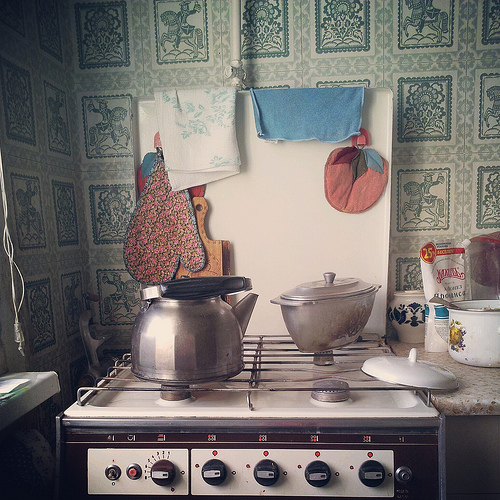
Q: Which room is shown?
A: It is a kitchen.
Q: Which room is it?
A: It is a kitchen.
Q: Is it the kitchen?
A: Yes, it is the kitchen.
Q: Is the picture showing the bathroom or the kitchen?
A: It is showing the kitchen.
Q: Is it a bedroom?
A: No, it is a kitchen.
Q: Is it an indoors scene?
A: Yes, it is indoors.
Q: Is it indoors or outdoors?
A: It is indoors.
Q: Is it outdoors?
A: No, it is indoors.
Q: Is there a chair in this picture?
A: No, there are no chairs.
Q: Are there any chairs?
A: No, there are no chairs.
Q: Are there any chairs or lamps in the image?
A: No, there are no chairs or lamps.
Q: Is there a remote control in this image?
A: Yes, there is a remote control.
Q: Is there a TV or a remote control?
A: Yes, there is a remote control.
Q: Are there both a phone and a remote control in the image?
A: No, there is a remote control but no phones.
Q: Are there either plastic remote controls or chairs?
A: Yes, there is a plastic remote control.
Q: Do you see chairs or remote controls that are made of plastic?
A: Yes, the remote control is made of plastic.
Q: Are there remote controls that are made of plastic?
A: Yes, there is a remote control that is made of plastic.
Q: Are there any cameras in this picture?
A: No, there are no cameras.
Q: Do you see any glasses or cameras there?
A: No, there are no cameras or glasses.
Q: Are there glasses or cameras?
A: No, there are no cameras or glasses.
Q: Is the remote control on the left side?
A: Yes, the remote control is on the left of the image.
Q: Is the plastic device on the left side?
A: Yes, the remote control is on the left of the image.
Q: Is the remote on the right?
A: No, the remote is on the left of the image.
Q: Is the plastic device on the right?
A: No, the remote is on the left of the image.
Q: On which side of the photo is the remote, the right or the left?
A: The remote is on the left of the image.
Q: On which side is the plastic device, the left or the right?
A: The remote is on the left of the image.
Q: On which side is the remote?
A: The remote is on the left of the image.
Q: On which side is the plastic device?
A: The remote is on the left of the image.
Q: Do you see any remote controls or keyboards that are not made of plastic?
A: No, there is a remote control but it is made of plastic.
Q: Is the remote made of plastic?
A: Yes, the remote is made of plastic.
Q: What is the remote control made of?
A: The remote control is made of plastic.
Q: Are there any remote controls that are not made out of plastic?
A: No, there is a remote control but it is made of plastic.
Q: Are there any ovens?
A: Yes, there is an oven.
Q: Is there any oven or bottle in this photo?
A: Yes, there is an oven.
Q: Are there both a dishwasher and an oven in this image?
A: No, there is an oven but no dishwashers.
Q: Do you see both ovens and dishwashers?
A: No, there is an oven but no dishwashers.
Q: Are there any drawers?
A: No, there are no drawers.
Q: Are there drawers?
A: No, there are no drawers.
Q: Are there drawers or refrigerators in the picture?
A: No, there are no drawers or refrigerators.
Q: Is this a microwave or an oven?
A: This is an oven.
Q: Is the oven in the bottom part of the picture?
A: Yes, the oven is in the bottom of the image.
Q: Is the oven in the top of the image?
A: No, the oven is in the bottom of the image.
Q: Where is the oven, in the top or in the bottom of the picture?
A: The oven is in the bottom of the image.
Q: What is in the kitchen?
A: The oven is in the kitchen.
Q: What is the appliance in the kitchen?
A: The appliance is an oven.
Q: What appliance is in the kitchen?
A: The appliance is an oven.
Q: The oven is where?
A: The oven is in the kitchen.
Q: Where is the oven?
A: The oven is in the kitchen.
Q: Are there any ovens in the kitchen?
A: Yes, there is an oven in the kitchen.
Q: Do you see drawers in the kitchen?
A: No, there is an oven in the kitchen.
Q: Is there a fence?
A: No, there are no fences.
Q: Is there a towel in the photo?
A: Yes, there is a towel.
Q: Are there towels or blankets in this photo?
A: Yes, there is a towel.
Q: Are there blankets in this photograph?
A: No, there are no blankets.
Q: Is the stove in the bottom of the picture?
A: Yes, the stove is in the bottom of the image.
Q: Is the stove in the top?
A: No, the stove is in the bottom of the image.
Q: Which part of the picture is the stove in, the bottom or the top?
A: The stove is in the bottom of the image.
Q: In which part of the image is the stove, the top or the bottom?
A: The stove is in the bottom of the image.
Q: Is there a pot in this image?
A: Yes, there is a pot.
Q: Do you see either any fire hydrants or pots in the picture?
A: Yes, there is a pot.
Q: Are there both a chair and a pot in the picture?
A: No, there is a pot but no chairs.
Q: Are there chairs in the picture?
A: No, there are no chairs.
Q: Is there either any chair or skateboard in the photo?
A: No, there are no chairs or skateboards.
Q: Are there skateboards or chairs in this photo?
A: No, there are no chairs or skateboards.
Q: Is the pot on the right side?
A: Yes, the pot is on the right of the image.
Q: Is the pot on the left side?
A: No, the pot is on the right of the image.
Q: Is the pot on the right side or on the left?
A: The pot is on the right of the image.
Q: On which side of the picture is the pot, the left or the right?
A: The pot is on the right of the image.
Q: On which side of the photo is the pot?
A: The pot is on the right of the image.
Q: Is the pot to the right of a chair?
A: No, the pot is to the right of the container.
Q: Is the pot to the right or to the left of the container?
A: The pot is to the right of the container.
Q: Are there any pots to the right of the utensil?
A: Yes, there is a pot to the right of the utensil.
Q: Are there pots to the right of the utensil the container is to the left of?
A: Yes, there is a pot to the right of the utensil.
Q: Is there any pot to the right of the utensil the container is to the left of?
A: Yes, there is a pot to the right of the utensil.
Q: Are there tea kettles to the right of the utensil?
A: No, there is a pot to the right of the utensil.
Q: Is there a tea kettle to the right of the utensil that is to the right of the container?
A: No, there is a pot to the right of the utensil.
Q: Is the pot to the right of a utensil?
A: Yes, the pot is to the right of a utensil.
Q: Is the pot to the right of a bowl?
A: No, the pot is to the right of a utensil.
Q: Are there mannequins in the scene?
A: No, there are no mannequins.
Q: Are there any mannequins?
A: No, there are no mannequins.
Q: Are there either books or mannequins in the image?
A: No, there are no mannequins or books.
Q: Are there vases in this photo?
A: No, there are no vases.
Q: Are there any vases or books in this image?
A: No, there are no vases or books.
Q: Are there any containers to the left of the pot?
A: Yes, there is a container to the left of the pot.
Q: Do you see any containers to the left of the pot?
A: Yes, there is a container to the left of the pot.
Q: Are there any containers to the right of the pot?
A: No, the container is to the left of the pot.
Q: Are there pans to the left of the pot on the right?
A: No, there is a container to the left of the pot.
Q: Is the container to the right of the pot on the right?
A: No, the container is to the left of the pot.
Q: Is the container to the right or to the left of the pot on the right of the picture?
A: The container is to the left of the pot.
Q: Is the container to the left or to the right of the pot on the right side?
A: The container is to the left of the pot.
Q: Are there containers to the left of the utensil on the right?
A: Yes, there is a container to the left of the utensil.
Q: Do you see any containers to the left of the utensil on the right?
A: Yes, there is a container to the left of the utensil.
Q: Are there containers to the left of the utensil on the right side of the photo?
A: Yes, there is a container to the left of the utensil.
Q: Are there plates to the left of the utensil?
A: No, there is a container to the left of the utensil.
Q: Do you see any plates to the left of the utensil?
A: No, there is a container to the left of the utensil.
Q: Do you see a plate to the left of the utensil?
A: No, there is a container to the left of the utensil.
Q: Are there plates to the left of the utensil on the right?
A: No, there is a container to the left of the utensil.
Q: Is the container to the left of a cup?
A: No, the container is to the left of a utensil.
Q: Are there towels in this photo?
A: Yes, there is a towel.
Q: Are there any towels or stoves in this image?
A: Yes, there is a towel.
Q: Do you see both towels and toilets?
A: No, there is a towel but no toilets.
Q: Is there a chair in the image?
A: No, there are no chairs.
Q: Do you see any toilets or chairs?
A: No, there are no chairs or toilets.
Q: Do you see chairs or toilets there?
A: No, there are no chairs or toilets.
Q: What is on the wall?
A: The towel is on the wall.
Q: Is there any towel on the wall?
A: Yes, there is a towel on the wall.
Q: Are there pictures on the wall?
A: No, there is a towel on the wall.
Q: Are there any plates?
A: No, there are no plates.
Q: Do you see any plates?
A: No, there are no plates.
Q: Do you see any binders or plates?
A: No, there are no plates or binders.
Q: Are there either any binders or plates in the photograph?
A: No, there are no plates or binders.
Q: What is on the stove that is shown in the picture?
A: The lid is on the stove.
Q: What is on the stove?
A: The lid is on the stove.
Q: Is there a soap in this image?
A: No, there are no soaps.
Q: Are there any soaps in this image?
A: No, there are no soaps.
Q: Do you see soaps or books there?
A: No, there are no soaps or books.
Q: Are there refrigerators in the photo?
A: No, there are no refrigerators.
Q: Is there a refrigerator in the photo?
A: No, there are no refrigerators.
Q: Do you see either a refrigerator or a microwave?
A: No, there are no refrigerators or microwaves.